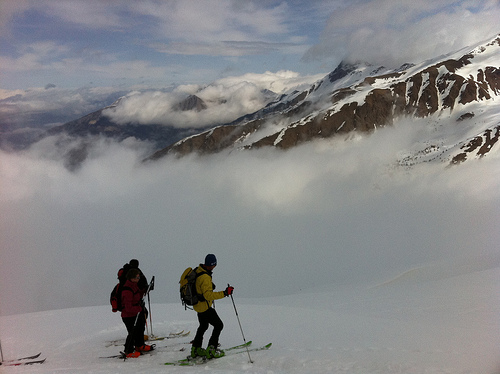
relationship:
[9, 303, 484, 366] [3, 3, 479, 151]
snow under sky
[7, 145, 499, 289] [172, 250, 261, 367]
clouds near man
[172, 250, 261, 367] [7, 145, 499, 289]
man near clouds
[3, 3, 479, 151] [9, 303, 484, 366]
sky above snow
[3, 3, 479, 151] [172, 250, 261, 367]
sky above man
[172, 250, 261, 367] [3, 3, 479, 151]
man under sky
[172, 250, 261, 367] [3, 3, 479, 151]
man below sky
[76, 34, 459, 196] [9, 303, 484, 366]
mountain covered in snow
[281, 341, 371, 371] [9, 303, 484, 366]
tracks in snow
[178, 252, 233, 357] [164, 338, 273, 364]
man standing on skis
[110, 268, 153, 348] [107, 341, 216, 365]
person standing on skis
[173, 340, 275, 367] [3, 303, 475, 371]
skis in snow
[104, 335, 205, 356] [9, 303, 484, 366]
skis in snow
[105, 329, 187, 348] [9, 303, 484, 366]
skis in snow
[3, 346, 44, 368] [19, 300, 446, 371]
skis in snow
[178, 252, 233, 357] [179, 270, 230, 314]
man in coat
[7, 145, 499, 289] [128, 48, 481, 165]
clouds above mountians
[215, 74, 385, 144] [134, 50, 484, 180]
snow on mountians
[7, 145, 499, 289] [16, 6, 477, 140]
clouds in sky